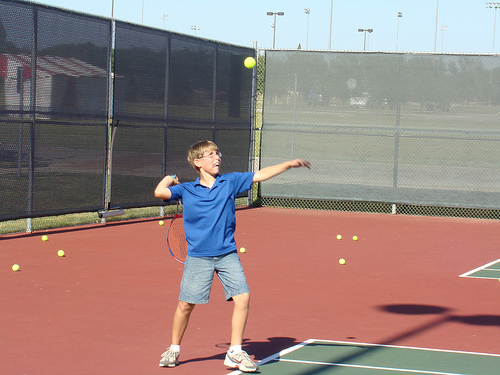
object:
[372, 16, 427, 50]
clouds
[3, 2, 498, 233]
fence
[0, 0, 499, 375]
tennis court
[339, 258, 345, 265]
tennis ball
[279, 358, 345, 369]
lines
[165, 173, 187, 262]
racket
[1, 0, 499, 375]
blue skies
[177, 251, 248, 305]
blue shorts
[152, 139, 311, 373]
boy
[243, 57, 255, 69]
tennis ball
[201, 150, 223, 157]
glasses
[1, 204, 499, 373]
claycourt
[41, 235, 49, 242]
tennis ball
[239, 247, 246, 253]
tennis ball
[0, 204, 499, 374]
ground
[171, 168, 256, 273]
lamb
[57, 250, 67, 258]
balls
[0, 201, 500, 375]
floor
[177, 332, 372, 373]
shadow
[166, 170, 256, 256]
blue shirt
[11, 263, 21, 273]
balls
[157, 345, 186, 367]
sneakers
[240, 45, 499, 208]
netting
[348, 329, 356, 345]
shadow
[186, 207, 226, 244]
blue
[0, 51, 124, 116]
screen